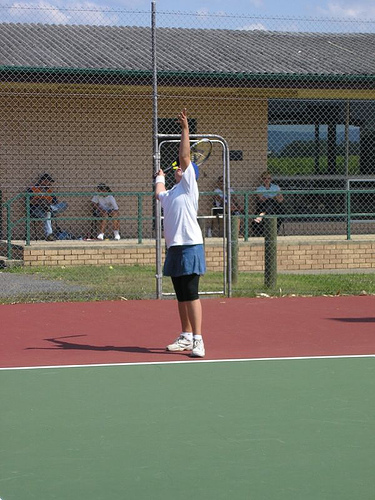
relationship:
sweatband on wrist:
[151, 173, 167, 185] [151, 175, 169, 183]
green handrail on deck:
[249, 187, 372, 194] [281, 228, 372, 245]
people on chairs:
[18, 170, 123, 244] [20, 211, 118, 239]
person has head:
[154, 107, 206, 358] [163, 155, 204, 187]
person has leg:
[154, 107, 206, 358] [175, 244, 206, 359]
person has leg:
[160, 134, 224, 314] [167, 277, 192, 352]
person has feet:
[154, 107, 206, 358] [161, 331, 221, 361]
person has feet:
[154, 107, 206, 358] [152, 334, 216, 359]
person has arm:
[154, 107, 206, 358] [153, 167, 169, 202]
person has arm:
[154, 107, 206, 358] [176, 104, 196, 175]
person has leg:
[90, 180, 122, 239] [96, 210, 108, 239]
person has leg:
[254, 172, 284, 235] [253, 198, 267, 223]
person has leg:
[211, 175, 245, 238] [234, 210, 239, 235]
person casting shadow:
[154, 107, 206, 358] [24, 333, 195, 356]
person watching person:
[254, 170, 284, 235] [154, 107, 206, 358]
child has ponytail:
[88, 178, 122, 241] [97, 181, 112, 193]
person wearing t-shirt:
[154, 107, 206, 358] [158, 161, 203, 246]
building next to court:
[5, 23, 373, 268] [0, 296, 373, 498]